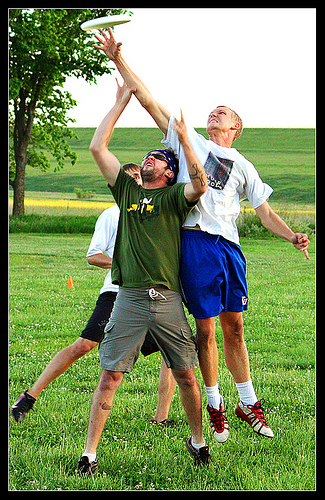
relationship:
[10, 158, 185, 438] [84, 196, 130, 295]
man in shirt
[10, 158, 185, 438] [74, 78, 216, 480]
man behind man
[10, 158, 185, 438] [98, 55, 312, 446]
man behind man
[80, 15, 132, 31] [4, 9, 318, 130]
frisbee in air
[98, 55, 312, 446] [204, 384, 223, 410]
man in socks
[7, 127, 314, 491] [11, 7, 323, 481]
grass covering field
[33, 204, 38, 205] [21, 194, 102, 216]
flower growing in field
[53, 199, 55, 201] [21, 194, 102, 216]
flower growing in field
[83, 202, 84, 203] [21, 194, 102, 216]
flower growing in field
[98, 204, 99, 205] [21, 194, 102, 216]
flower growing in field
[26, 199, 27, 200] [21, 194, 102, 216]
flower growing in field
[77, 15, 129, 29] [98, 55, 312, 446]
frisbee flying above man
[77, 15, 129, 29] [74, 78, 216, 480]
frisbee flying above man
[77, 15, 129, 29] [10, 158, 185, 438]
frisbee flying above man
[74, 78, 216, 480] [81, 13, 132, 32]
man reaching for frisbee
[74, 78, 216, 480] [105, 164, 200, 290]
man wearing shirt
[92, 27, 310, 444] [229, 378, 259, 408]
man wearing sock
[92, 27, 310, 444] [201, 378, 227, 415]
man wearing sock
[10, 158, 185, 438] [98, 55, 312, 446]
man standing behind man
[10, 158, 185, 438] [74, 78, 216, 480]
man standing behind man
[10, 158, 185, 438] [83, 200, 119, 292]
man wearing shirt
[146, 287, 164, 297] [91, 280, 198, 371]
knot tying shorts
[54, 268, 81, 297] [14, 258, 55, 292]
cone standing in grass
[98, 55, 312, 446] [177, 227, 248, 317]
man wearing shorts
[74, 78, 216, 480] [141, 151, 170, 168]
man wearing sunglasses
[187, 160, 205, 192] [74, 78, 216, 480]
tattoo inked on man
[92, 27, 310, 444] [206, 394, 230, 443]
man wearing athletic shoe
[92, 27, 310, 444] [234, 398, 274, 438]
man wearing athletic shoe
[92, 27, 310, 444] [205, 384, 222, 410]
man wearing sock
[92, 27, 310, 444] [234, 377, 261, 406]
man wearing sock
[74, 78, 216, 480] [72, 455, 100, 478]
man wearing shoe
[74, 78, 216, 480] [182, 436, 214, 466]
man wearing shoe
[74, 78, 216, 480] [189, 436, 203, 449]
man wearing sock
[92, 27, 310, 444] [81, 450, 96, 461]
man wearing sock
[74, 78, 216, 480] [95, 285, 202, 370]
man wearing shorts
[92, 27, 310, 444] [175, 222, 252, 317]
man wearing shorts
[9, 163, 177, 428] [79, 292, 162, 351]
man wearing shorts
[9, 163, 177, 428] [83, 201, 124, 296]
man wearing shirt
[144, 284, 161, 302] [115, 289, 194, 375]
drawstring on shorts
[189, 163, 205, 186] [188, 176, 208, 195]
tattoo on forearm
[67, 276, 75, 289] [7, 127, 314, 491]
cone sitting in grass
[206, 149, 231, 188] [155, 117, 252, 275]
design printed on tshirt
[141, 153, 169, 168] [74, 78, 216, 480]
sunglasses worn by man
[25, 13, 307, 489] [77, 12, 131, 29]
men trying to catch frisbee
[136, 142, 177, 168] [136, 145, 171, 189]
sunglasses on face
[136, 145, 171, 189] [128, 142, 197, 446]
face on man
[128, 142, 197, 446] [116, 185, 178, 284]
man in shirt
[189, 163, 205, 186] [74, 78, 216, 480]
tattoo on man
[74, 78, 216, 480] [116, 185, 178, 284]
man in shirt